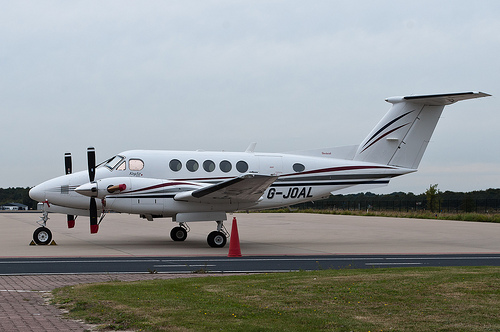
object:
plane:
[22, 145, 446, 244]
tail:
[317, 84, 500, 179]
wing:
[174, 170, 280, 213]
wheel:
[27, 226, 60, 250]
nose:
[26, 163, 99, 217]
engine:
[70, 175, 221, 214]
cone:
[223, 215, 244, 260]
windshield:
[101, 154, 128, 171]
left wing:
[174, 170, 285, 210]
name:
[267, 185, 318, 203]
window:
[165, 155, 186, 176]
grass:
[46, 262, 499, 332]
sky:
[0, 1, 497, 70]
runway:
[0, 239, 464, 261]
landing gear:
[26, 210, 235, 250]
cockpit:
[103, 155, 141, 175]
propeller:
[86, 193, 103, 237]